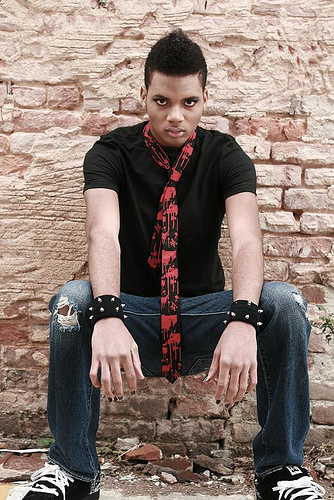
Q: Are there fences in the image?
A: No, there are no fences.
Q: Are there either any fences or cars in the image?
A: No, there are no fences or cars.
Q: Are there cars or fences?
A: No, there are no fences or cars.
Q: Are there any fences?
A: No, there are no fences.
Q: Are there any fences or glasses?
A: No, there are no fences or glasses.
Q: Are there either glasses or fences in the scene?
A: No, there are no fences or glasses.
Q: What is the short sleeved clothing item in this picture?
A: The clothing item is a shirt.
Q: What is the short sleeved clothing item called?
A: The clothing item is a shirt.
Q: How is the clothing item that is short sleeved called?
A: The clothing item is a shirt.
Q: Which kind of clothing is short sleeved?
A: The clothing is a shirt.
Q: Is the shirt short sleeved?
A: Yes, the shirt is short sleeved.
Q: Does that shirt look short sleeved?
A: Yes, the shirt is short sleeved.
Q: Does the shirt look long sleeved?
A: No, the shirt is short sleeved.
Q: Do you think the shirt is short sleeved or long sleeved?
A: The shirt is short sleeved.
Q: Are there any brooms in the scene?
A: No, there are no brooms.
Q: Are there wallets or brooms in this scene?
A: No, there are no brooms or wallets.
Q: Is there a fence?
A: No, there are no fences.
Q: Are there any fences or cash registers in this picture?
A: No, there are no fences or cash registers.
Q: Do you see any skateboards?
A: No, there are no skateboards.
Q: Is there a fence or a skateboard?
A: No, there are no skateboards or fences.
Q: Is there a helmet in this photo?
A: No, there are no helmets.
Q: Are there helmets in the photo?
A: No, there are no helmets.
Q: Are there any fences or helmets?
A: No, there are no helmets or fences.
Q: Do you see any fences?
A: No, there are no fences.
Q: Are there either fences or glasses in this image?
A: No, there are no fences or glasses.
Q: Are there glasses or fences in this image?
A: No, there are no fences or glasses.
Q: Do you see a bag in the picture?
A: No, there are no bags.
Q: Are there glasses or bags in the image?
A: No, there are no bags or glasses.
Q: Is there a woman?
A: No, there are no women.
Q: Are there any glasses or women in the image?
A: No, there are no women or glasses.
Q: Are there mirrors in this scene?
A: No, there are no mirrors.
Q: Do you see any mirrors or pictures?
A: No, there are no mirrors or pictures.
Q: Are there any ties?
A: Yes, there is a tie.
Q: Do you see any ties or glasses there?
A: Yes, there is a tie.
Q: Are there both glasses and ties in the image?
A: No, there is a tie but no glasses.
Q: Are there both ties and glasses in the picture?
A: No, there is a tie but no glasses.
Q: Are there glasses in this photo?
A: No, there are no glasses.